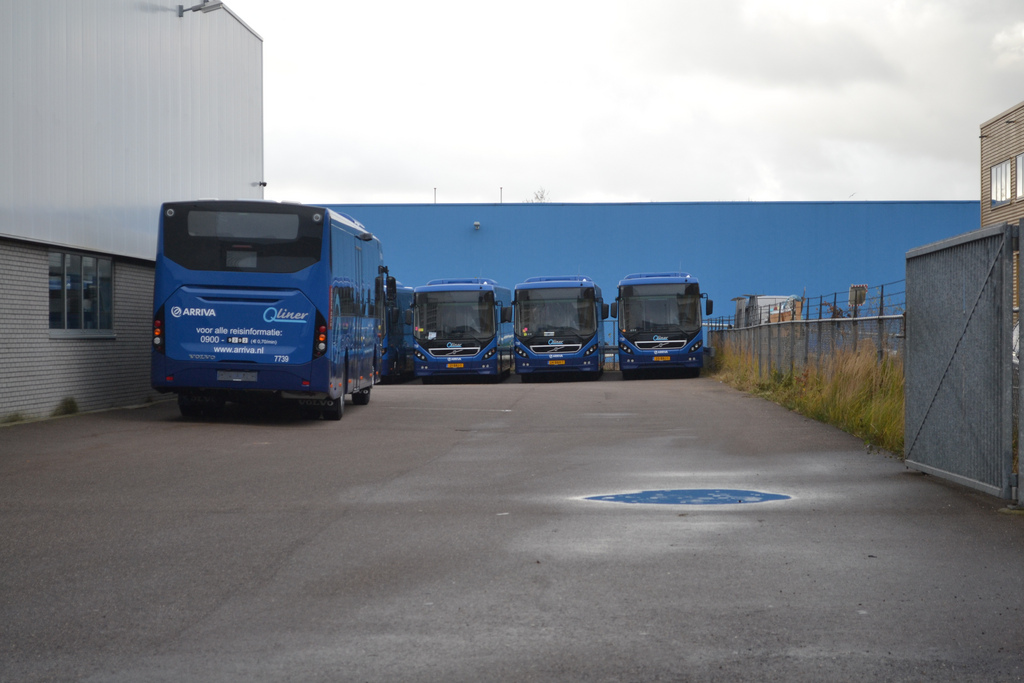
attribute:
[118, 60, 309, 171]
building — tan